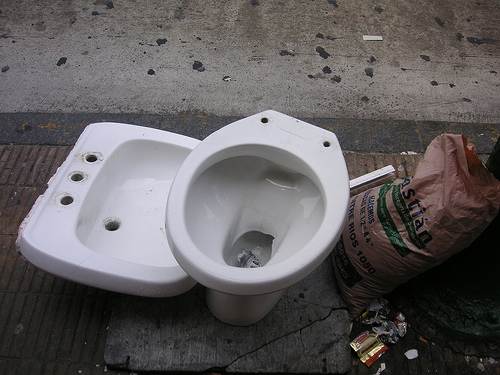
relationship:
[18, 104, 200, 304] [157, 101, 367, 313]
sink left of toilet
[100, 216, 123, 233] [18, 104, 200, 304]
drain hole on sink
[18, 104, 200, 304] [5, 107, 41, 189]
sink on pavement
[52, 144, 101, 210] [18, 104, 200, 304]
three holes drilled into sink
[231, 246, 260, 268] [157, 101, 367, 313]
gray object inside toilet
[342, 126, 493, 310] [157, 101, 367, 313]
brown bag next to toilet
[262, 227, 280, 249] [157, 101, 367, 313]
crack if front of toilet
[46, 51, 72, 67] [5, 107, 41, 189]
black spot on pavement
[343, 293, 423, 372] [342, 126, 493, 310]
litter next to brown bag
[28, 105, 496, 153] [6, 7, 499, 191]
dark line on sidewalk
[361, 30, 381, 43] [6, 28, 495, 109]
white paper on street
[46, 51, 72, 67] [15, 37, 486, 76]
black spot on road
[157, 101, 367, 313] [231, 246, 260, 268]
toilet with an gray object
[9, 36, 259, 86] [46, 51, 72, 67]
concrete with black spot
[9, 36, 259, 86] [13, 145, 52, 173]
concrete with grate pattern